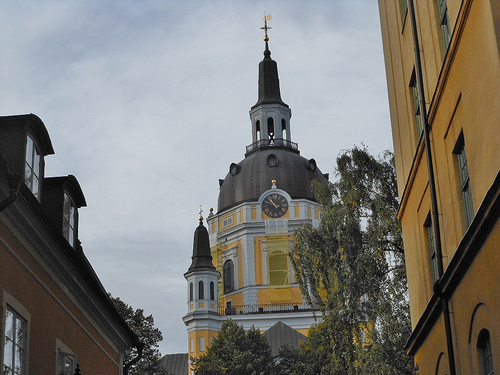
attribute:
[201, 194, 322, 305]
wall — yellow in color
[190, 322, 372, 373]
wall — black, yellow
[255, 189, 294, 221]
clock — big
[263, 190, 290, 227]
black clock — yellow, big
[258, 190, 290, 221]
clock — big, yellow, black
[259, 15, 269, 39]
cross — part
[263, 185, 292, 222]
clock — big, yellow, black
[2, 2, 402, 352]
clouds — thick, white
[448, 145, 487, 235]
window — part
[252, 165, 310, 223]
clock — big, yellow, black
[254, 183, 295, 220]
clock — big, yellow, black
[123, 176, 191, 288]
clud — part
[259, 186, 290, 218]
clock — black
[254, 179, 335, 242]
clock — black, blue, yellow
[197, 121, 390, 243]
dome — black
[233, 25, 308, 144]
top — sharp